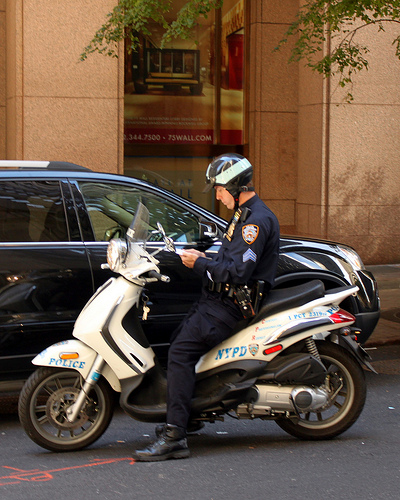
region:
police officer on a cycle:
[20, 145, 373, 469]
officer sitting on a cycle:
[14, 147, 373, 467]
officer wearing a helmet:
[18, 149, 376, 471]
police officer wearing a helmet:
[20, 149, 372, 467]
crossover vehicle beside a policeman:
[0, 153, 380, 395]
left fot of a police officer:
[126, 423, 197, 493]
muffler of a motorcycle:
[251, 376, 335, 418]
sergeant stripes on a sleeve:
[234, 245, 260, 269]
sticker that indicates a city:
[208, 344, 247, 365]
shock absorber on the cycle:
[68, 349, 106, 424]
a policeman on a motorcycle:
[17, 149, 377, 463]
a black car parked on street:
[0, 159, 385, 415]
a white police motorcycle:
[15, 199, 379, 454]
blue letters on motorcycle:
[211, 343, 248, 361]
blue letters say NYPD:
[213, 345, 246, 359]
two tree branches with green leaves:
[72, 0, 399, 112]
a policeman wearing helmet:
[200, 151, 256, 210]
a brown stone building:
[0, 0, 398, 265]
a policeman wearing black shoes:
[131, 418, 206, 463]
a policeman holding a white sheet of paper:
[165, 237, 216, 284]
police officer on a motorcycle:
[10, 129, 383, 466]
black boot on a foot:
[129, 421, 189, 463]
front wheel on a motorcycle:
[16, 355, 113, 459]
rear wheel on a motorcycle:
[260, 334, 374, 442]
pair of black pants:
[168, 283, 249, 428]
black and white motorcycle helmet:
[201, 149, 254, 200]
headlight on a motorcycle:
[102, 239, 118, 270]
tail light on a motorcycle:
[327, 305, 359, 327]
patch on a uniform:
[240, 222, 262, 245]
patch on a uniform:
[239, 245, 259, 265]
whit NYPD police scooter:
[9, 200, 379, 454]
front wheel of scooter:
[16, 365, 114, 455]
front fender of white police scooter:
[27, 338, 127, 395]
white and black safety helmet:
[200, 149, 253, 195]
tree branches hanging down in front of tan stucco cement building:
[72, 0, 398, 109]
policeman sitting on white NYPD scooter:
[15, 151, 380, 463]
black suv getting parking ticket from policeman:
[1, 153, 379, 463]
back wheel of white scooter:
[272, 336, 371, 444]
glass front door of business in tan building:
[106, 0, 267, 152]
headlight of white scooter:
[100, 232, 142, 272]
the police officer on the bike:
[135, 149, 280, 461]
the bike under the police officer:
[17, 200, 381, 453]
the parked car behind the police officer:
[0, 159, 381, 389]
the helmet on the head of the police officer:
[199, 153, 255, 206]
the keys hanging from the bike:
[140, 295, 150, 323]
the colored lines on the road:
[0, 455, 137, 488]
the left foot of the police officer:
[128, 425, 193, 463]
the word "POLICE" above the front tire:
[47, 357, 89, 369]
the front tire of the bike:
[18, 365, 114, 450]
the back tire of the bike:
[271, 338, 365, 439]